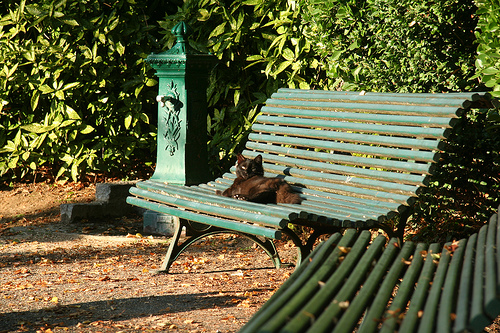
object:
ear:
[254, 153, 267, 163]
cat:
[214, 153, 301, 205]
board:
[126, 196, 281, 242]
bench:
[125, 89, 493, 274]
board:
[250, 122, 440, 151]